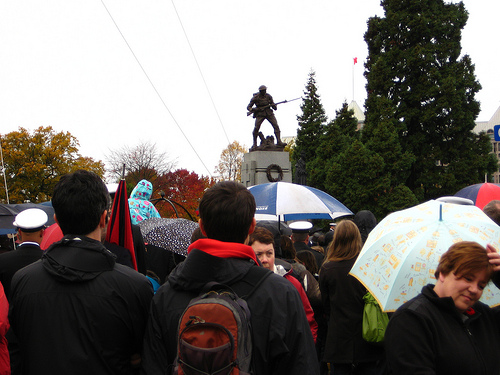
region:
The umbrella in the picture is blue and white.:
[260, 180, 345, 223]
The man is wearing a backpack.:
[180, 277, 275, 372]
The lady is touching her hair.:
[430, 232, 496, 293]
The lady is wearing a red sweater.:
[255, 233, 290, 270]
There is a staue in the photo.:
[241, 77, 306, 150]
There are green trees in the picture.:
[291, 67, 428, 178]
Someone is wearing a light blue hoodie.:
[127, 180, 169, 216]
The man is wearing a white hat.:
[15, 205, 65, 245]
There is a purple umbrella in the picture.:
[140, 213, 210, 253]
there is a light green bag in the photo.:
[362, 293, 392, 343]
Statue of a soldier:
[231, 67, 316, 189]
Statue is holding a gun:
[232, 73, 294, 190]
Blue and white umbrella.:
[205, 170, 369, 223]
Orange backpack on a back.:
[143, 252, 278, 370]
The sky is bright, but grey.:
[3, 0, 495, 187]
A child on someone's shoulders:
[119, 162, 173, 228]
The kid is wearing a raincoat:
[120, 173, 169, 229]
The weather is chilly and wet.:
[14, 0, 495, 367]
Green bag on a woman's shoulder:
[355, 280, 400, 351]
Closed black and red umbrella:
[92, 152, 148, 277]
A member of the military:
[3, 206, 49, 276]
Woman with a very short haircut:
[377, 241, 499, 374]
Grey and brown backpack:
[171, 291, 253, 373]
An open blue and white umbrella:
[235, 180, 355, 220]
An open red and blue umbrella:
[455, 175, 496, 210]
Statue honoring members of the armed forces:
[240, 80, 295, 180]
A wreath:
[260, 160, 285, 180]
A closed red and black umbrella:
[101, 165, 137, 265]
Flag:
[348, 51, 362, 96]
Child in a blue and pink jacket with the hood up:
[123, 173, 166, 226]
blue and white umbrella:
[211, 148, 388, 252]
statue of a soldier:
[241, 77, 295, 167]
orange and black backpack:
[167, 268, 269, 370]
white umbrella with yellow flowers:
[350, 128, 497, 303]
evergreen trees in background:
[275, 20, 452, 174]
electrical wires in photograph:
[81, 8, 291, 159]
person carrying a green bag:
[320, 282, 414, 344]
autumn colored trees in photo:
[107, 154, 231, 225]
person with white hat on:
[1, 195, 62, 247]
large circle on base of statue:
[251, 150, 288, 191]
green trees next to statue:
[301, 0, 497, 211]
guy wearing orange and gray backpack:
[151, 180, 318, 373]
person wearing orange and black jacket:
[151, 174, 322, 374]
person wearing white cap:
[0, 208, 51, 295]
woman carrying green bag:
[318, 217, 387, 374]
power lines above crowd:
[96, 0, 253, 185]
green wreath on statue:
[264, 160, 286, 182]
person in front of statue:
[143, 78, 318, 373]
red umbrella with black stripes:
[107, 158, 141, 280]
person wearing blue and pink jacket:
[123, 175, 166, 232]